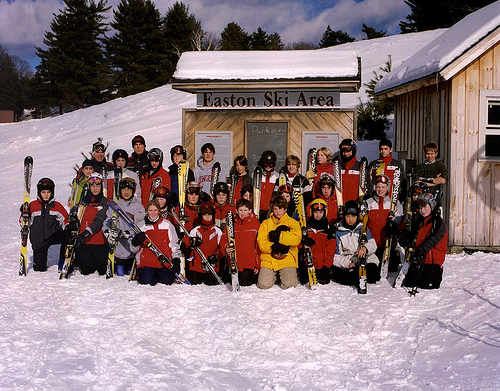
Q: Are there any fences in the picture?
A: No, there are no fences.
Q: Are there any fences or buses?
A: No, there are no fences or buses.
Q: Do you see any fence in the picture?
A: No, there are no fences.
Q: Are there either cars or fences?
A: No, there are no fences or cars.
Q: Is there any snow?
A: Yes, there is snow.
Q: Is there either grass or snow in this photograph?
A: Yes, there is snow.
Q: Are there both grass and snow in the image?
A: No, there is snow but no grass.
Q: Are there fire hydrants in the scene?
A: No, there are no fire hydrants.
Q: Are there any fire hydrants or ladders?
A: No, there are no fire hydrants or ladders.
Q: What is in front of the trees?
A: The snow is in front of the trees.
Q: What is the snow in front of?
A: The snow is in front of the trees.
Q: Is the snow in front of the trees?
A: Yes, the snow is in front of the trees.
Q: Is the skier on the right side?
A: Yes, the skier is on the right of the image.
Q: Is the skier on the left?
A: No, the skier is on the right of the image.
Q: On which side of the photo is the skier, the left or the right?
A: The skier is on the right of the image.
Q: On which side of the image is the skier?
A: The skier is on the right of the image.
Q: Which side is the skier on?
A: The skier is on the right of the image.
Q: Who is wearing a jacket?
A: The skier is wearing a jacket.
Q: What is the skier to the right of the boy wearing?
A: The skier is wearing a jacket.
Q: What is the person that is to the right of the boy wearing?
A: The skier is wearing a jacket.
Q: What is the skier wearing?
A: The skier is wearing a jacket.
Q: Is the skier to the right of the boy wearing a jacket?
A: Yes, the skier is wearing a jacket.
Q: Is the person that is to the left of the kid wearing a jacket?
A: Yes, the skier is wearing a jacket.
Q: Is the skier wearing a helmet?
A: No, the skier is wearing a jacket.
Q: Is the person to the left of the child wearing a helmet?
A: No, the skier is wearing a jacket.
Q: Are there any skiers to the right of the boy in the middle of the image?
A: Yes, there is a skier to the right of the boy.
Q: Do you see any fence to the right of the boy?
A: No, there is a skier to the right of the boy.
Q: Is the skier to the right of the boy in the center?
A: Yes, the skier is to the right of the boy.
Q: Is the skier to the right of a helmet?
A: No, the skier is to the right of the boy.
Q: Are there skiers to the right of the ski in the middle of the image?
A: Yes, there is a skier to the right of the ski.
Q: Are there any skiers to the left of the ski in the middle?
A: No, the skier is to the right of the ski.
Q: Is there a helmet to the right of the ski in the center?
A: No, there is a skier to the right of the ski.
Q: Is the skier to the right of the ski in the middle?
A: Yes, the skier is to the right of the ski.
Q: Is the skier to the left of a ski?
A: No, the skier is to the right of a ski.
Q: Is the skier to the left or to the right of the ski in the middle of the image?
A: The skier is to the right of the ski.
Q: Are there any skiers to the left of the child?
A: Yes, there is a skier to the left of the child.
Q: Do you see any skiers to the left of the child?
A: Yes, there is a skier to the left of the child.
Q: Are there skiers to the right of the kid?
A: No, the skier is to the left of the kid.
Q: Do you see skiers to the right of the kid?
A: No, the skier is to the left of the kid.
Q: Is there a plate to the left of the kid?
A: No, there is a skier to the left of the kid.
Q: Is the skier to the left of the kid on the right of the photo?
A: Yes, the skier is to the left of the kid.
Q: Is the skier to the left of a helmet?
A: No, the skier is to the left of the kid.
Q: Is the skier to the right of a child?
A: No, the skier is to the left of a child.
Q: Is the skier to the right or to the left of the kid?
A: The skier is to the left of the kid.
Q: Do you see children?
A: Yes, there is a child.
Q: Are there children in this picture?
A: Yes, there is a child.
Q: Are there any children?
A: Yes, there is a child.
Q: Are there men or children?
A: Yes, there is a child.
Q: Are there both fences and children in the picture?
A: No, there is a child but no fences.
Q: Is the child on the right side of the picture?
A: Yes, the child is on the right of the image.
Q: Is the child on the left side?
A: No, the child is on the right of the image.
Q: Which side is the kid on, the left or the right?
A: The kid is on the right of the image.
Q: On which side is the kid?
A: The kid is on the right of the image.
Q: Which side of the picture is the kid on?
A: The kid is on the right of the image.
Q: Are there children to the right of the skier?
A: Yes, there is a child to the right of the skier.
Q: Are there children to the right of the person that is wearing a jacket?
A: Yes, there is a child to the right of the skier.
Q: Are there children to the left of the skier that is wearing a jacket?
A: No, the child is to the right of the skier.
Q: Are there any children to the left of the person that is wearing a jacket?
A: No, the child is to the right of the skier.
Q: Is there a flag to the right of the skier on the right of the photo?
A: No, there is a child to the right of the skier.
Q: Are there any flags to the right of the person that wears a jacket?
A: No, there is a child to the right of the skier.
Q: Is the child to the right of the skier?
A: Yes, the child is to the right of the skier.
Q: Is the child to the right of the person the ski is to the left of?
A: Yes, the child is to the right of the skier.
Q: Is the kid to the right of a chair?
A: No, the kid is to the right of the skier.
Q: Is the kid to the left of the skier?
A: No, the kid is to the right of the skier.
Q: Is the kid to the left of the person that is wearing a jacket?
A: No, the kid is to the right of the skier.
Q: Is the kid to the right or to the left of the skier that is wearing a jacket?
A: The kid is to the right of the skier.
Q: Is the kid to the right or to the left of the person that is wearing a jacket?
A: The kid is to the right of the skier.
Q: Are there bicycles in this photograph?
A: No, there are no bicycles.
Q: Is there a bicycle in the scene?
A: No, there are no bicycles.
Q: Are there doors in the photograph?
A: Yes, there is a door.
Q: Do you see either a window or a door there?
A: Yes, there is a door.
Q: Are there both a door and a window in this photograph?
A: Yes, there are both a door and a window.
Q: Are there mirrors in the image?
A: No, there are no mirrors.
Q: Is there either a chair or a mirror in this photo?
A: No, there are no mirrors or chairs.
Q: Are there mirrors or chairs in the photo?
A: No, there are no mirrors or chairs.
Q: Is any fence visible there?
A: No, there are no fences.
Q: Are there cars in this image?
A: No, there are no cars.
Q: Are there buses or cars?
A: No, there are no cars or buses.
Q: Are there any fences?
A: No, there are no fences.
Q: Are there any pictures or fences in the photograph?
A: No, there are no fences or pictures.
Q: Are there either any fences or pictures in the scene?
A: No, there are no fences or pictures.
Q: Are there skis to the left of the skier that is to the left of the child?
A: Yes, there is a ski to the left of the skier.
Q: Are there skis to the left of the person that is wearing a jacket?
A: Yes, there is a ski to the left of the skier.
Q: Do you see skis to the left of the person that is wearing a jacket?
A: Yes, there is a ski to the left of the skier.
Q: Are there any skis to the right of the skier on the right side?
A: No, the ski is to the left of the skier.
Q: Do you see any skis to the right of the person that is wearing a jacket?
A: No, the ski is to the left of the skier.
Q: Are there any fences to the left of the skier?
A: No, there is a ski to the left of the skier.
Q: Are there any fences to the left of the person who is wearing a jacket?
A: No, there is a ski to the left of the skier.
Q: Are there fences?
A: No, there are no fences.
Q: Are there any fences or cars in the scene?
A: No, there are no fences or cars.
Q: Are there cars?
A: No, there are no cars.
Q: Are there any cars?
A: No, there are no cars.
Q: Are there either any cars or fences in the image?
A: No, there are no cars or fences.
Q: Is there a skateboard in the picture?
A: No, there are no skateboards.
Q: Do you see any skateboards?
A: No, there are no skateboards.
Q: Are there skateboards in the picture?
A: No, there are no skateboards.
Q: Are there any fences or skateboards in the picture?
A: No, there are no skateboards or fences.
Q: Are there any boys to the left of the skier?
A: Yes, there is a boy to the left of the skier.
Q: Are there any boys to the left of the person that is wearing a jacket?
A: Yes, there is a boy to the left of the skier.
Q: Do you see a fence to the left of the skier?
A: No, there is a boy to the left of the skier.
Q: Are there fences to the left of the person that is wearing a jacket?
A: No, there is a boy to the left of the skier.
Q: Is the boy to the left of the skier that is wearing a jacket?
A: Yes, the boy is to the left of the skier.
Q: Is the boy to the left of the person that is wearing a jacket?
A: Yes, the boy is to the left of the skier.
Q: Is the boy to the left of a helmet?
A: No, the boy is to the left of the skier.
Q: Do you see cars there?
A: No, there are no cars.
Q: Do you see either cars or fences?
A: No, there are no cars or fences.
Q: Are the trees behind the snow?
A: Yes, the trees are behind the snow.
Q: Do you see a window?
A: Yes, there is a window.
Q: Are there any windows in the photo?
A: Yes, there is a window.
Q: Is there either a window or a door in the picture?
A: Yes, there is a window.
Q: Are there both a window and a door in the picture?
A: Yes, there are both a window and a door.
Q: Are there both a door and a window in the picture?
A: Yes, there are both a window and a door.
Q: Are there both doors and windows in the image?
A: Yes, there are both a window and a door.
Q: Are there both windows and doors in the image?
A: Yes, there are both a window and a door.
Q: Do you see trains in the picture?
A: No, there are no trains.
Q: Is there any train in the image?
A: No, there are no trains.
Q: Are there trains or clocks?
A: No, there are no trains or clocks.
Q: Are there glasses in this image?
A: No, there are no glasses.